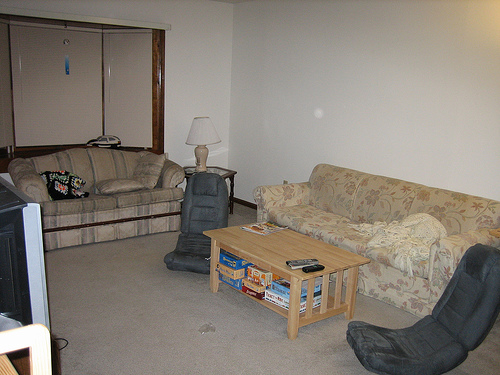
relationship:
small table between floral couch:
[180, 164, 237, 215] [251, 164, 498, 353]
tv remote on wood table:
[300, 264, 332, 277] [182, 165, 235, 216]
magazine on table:
[241, 221, 286, 237] [197, 216, 373, 339]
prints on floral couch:
[406, 180, 426, 203] [251, 149, 499, 354]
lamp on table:
[186, 112, 223, 171] [172, 164, 237, 273]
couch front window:
[1, 9, 170, 147] [2, 13, 172, 149]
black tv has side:
[0, 174, 51, 335] [4, 196, 29, 305]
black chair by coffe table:
[348, 230, 493, 374] [153, 196, 256, 277]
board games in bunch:
[215, 249, 326, 314] [213, 247, 327, 323]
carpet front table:
[42, 191, 499, 367] [197, 216, 373, 339]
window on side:
[1, 15, 23, 160] [146, 24, 169, 151]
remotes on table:
[286, 257, 327, 274] [282, 247, 329, 279]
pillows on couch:
[94, 150, 182, 200] [10, 133, 197, 256]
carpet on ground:
[42, 191, 499, 367] [33, 238, 369, 372]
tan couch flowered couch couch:
[254, 157, 499, 317] [8, 147, 185, 253]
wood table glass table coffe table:
[182, 160, 241, 216] [202, 221, 371, 338]